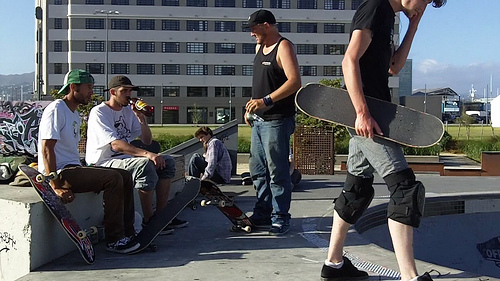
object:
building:
[392, 58, 414, 99]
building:
[400, 91, 444, 122]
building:
[489, 93, 500, 129]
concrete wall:
[0, 153, 186, 274]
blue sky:
[397, 0, 500, 64]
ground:
[13, 171, 500, 281]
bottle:
[126, 97, 152, 117]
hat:
[102, 75, 136, 93]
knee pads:
[382, 168, 426, 228]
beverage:
[127, 97, 153, 117]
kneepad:
[331, 170, 375, 225]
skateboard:
[122, 176, 203, 256]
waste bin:
[292, 122, 336, 176]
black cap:
[240, 8, 277, 29]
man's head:
[247, 8, 280, 46]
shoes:
[415, 271, 435, 281]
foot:
[318, 257, 373, 280]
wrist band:
[262, 94, 275, 108]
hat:
[56, 68, 96, 95]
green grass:
[79, 123, 500, 163]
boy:
[35, 67, 142, 255]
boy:
[83, 74, 191, 236]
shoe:
[319, 255, 369, 279]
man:
[240, 8, 305, 239]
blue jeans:
[248, 114, 297, 227]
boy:
[188, 126, 234, 184]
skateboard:
[292, 81, 446, 150]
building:
[31, 0, 402, 143]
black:
[249, 37, 297, 122]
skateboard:
[16, 163, 97, 265]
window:
[134, 17, 158, 31]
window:
[111, 17, 133, 30]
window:
[53, 17, 63, 30]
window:
[296, 21, 318, 33]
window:
[185, 85, 210, 98]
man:
[315, 0, 454, 281]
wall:
[0, 120, 238, 281]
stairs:
[182, 162, 185, 168]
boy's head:
[63, 67, 95, 105]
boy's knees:
[385, 172, 426, 212]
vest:
[251, 36, 297, 117]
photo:
[0, 0, 498, 280]